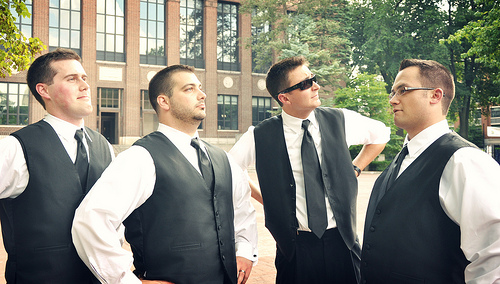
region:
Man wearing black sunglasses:
[264, 56, 322, 114]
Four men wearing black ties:
[3, 48, 492, 271]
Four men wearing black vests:
[5, 51, 495, 280]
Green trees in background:
[242, 0, 497, 150]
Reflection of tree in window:
[178, 7, 245, 71]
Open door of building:
[93, 85, 123, 145]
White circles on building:
[144, 70, 266, 91]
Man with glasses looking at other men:
[387, 57, 456, 131]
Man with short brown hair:
[27, 49, 97, 120]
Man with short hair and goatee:
[147, 62, 211, 124]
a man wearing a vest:
[357, 52, 498, 282]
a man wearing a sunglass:
[217, 50, 383, 280]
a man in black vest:
[73, 60, 261, 282]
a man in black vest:
[2, 47, 122, 282]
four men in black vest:
[2, 47, 499, 279]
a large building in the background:
[2, 1, 365, 166]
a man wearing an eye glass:
[356, 51, 498, 282]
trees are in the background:
[237, 3, 495, 178]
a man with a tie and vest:
[232, 57, 387, 282]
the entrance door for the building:
[97, 104, 122, 150]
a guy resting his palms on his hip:
[228, 58, 388, 283]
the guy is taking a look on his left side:
[233, 55, 388, 282]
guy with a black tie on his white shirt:
[230, 55, 390, 282]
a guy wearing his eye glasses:
[361, 58, 498, 282]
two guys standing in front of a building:
[1, 0, 238, 282]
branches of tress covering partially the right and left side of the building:
[1, 2, 356, 145]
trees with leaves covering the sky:
[350, 2, 471, 144]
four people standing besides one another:
[0, 45, 495, 277]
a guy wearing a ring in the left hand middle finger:
[71, 62, 256, 282]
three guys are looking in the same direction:
[2, 48, 390, 282]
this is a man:
[253, 62, 358, 250]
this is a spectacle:
[297, 65, 332, 95]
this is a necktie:
[301, 127, 326, 204]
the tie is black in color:
[302, 145, 329, 187]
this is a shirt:
[456, 171, 499, 251]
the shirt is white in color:
[463, 186, 490, 241]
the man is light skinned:
[396, 102, 435, 118]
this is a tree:
[380, 22, 441, 48]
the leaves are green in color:
[389, 22, 421, 57]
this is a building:
[96, 15, 186, 55]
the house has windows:
[106, 0, 178, 63]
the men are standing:
[26, 29, 488, 169]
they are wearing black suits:
[9, 22, 499, 277]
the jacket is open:
[219, 109, 364, 265]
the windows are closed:
[104, 13, 251, 60]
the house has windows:
[91, 3, 246, 66]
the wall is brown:
[132, 70, 143, 130]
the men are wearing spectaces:
[247, 29, 495, 254]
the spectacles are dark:
[243, 57, 355, 163]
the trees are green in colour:
[301, 20, 393, 67]